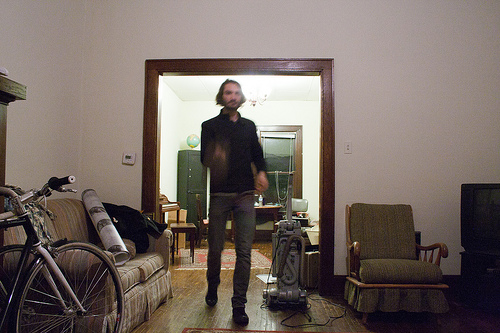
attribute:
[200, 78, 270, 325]
man — walking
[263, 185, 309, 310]
vacuum — gray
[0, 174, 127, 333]
bike — here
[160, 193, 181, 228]
piano — brown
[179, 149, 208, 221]
cabinet — green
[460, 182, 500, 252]
television — here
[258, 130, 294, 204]
window — here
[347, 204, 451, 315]
chair — green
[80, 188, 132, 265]
poster — rolled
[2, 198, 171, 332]
couch — here